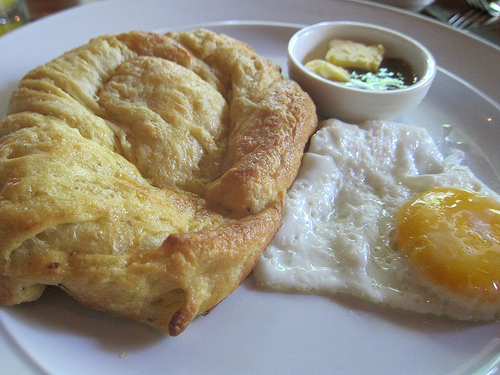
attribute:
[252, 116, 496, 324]
egg — white, fried, not an omelette, oily, yellow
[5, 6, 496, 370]
plate — white, off white, round, holding breakfast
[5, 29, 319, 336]
danish — lemon, tan, lemon flavored, lemon filled, a pastry, for breakfast, toasted, flaky, burnt, brown, crusty, large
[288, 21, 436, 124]
cup — white, small, bowl shaped, sauce tupe, sitting, sauce type, for sauce, round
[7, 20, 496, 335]
food — for breakfast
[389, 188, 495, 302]
yolk — round, yellow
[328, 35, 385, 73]
butter — a slice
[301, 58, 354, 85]
butter — a slice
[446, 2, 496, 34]
fork — silver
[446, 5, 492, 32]
prongs — at end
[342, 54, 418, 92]
syrup — for dipping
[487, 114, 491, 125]
reflection — from ceiling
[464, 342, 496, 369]
reflection — from ceiling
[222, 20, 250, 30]
reflection — from ceiling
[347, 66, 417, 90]
reflection — from light